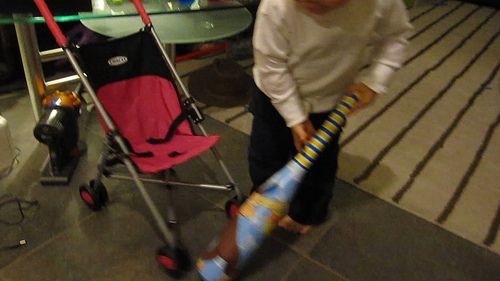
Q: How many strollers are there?
A: One.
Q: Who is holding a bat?
A: A child.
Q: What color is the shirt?
A: White.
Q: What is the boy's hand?
A: Bat.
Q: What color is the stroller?
A: Red.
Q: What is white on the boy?
A: Shirt.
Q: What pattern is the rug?
A: Striped.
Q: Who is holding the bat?
A: Boy.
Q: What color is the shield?
A: Clear.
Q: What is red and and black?
A: Stroller.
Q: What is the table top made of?
A: Glass.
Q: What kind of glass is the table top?
A: Frosted.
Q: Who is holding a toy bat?
A: The child.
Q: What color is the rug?
A: Tan and brown.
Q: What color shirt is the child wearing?
A: White.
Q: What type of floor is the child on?
A: Tile.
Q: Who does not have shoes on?
A: The child.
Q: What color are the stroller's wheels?
A: Red and black.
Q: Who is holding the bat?
A: The little boy.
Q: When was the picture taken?
A: Night time.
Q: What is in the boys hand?
A: A bat.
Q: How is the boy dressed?
A: A white shirt.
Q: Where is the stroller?
A: Beside the boy.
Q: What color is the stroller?
A: Red.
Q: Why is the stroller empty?
A: The boy is standing.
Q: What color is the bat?
A: Blue and yellow.